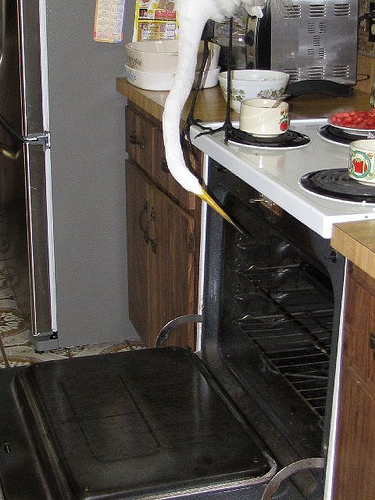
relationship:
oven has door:
[183, 142, 337, 467] [23, 346, 272, 499]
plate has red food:
[326, 116, 374, 135] [331, 105, 374, 127]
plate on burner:
[326, 116, 374, 135] [321, 124, 374, 144]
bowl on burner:
[239, 97, 291, 138] [226, 125, 308, 148]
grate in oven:
[233, 252, 330, 423] [0, 108, 373, 499]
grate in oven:
[233, 252, 338, 362] [0, 108, 373, 499]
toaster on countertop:
[208, 1, 359, 80] [330, 220, 373, 277]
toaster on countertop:
[208, 1, 359, 80] [115, 76, 373, 127]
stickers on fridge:
[85, 1, 185, 47] [1, 0, 141, 354]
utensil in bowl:
[272, 92, 292, 108] [236, 97, 290, 138]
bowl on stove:
[236, 97, 290, 138] [1, 107, 372, 498]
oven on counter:
[215, 0, 357, 98] [197, 91, 323, 111]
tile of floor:
[0, 340, 72, 367] [1, 204, 149, 378]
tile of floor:
[0, 295, 30, 342] [1, 204, 149, 378]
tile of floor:
[0, 259, 15, 300] [1, 204, 149, 378]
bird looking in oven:
[162, 0, 264, 237] [0, 108, 373, 499]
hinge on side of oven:
[258, 449, 332, 498] [161, 104, 365, 475]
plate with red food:
[326, 121, 375, 135] [329, 106, 374, 130]